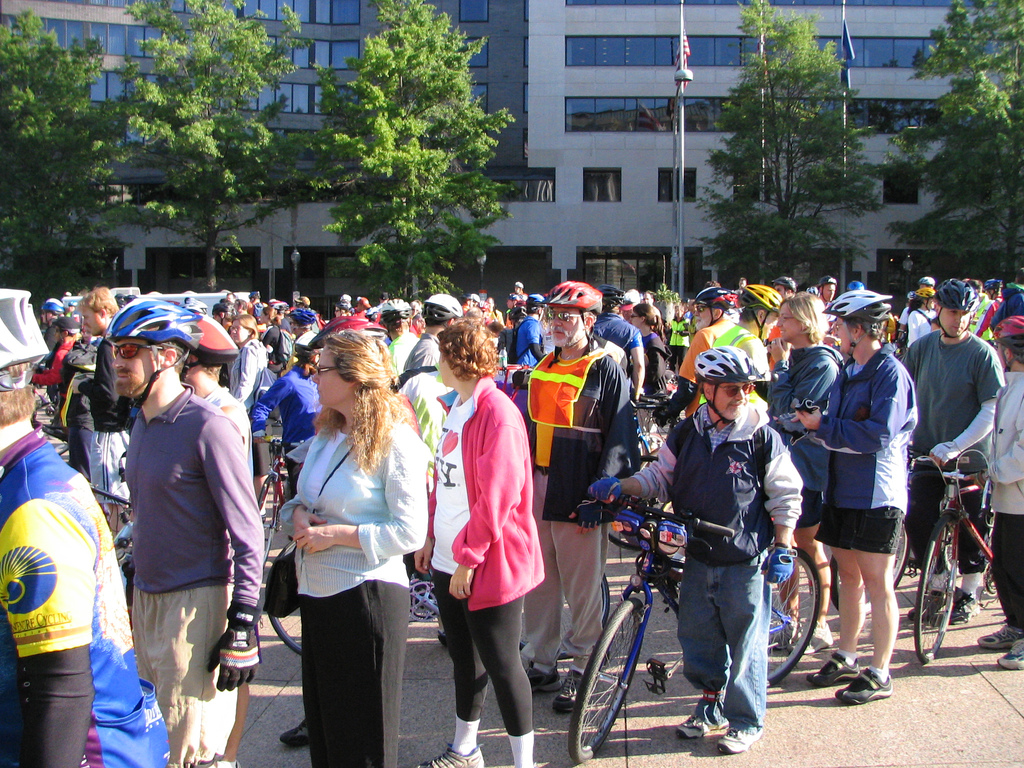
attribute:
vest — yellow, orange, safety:
[527, 328, 654, 446]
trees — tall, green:
[82, 55, 497, 233]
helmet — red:
[483, 277, 712, 490]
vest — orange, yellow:
[498, 369, 664, 494]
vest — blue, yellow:
[11, 470, 204, 755]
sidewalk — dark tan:
[796, 685, 996, 758]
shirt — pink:
[422, 403, 645, 637]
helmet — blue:
[82, 267, 299, 637]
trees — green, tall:
[142, 49, 1013, 288]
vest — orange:
[523, 345, 609, 469]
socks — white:
[441, 712, 544, 766]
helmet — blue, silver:
[94, 296, 215, 354]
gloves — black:
[582, 470, 804, 594]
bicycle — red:
[896, 448, 1018, 673]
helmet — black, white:
[817, 282, 898, 333]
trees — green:
[289, 2, 521, 293]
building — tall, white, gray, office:
[522, 2, 1022, 329]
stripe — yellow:
[529, 363, 588, 389]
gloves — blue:
[585, 463, 629, 509]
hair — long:
[350, 344, 387, 433]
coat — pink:
[475, 418, 542, 576]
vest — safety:
[520, 355, 609, 461]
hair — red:
[443, 340, 493, 371]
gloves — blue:
[751, 547, 803, 591]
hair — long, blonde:
[339, 370, 396, 448]